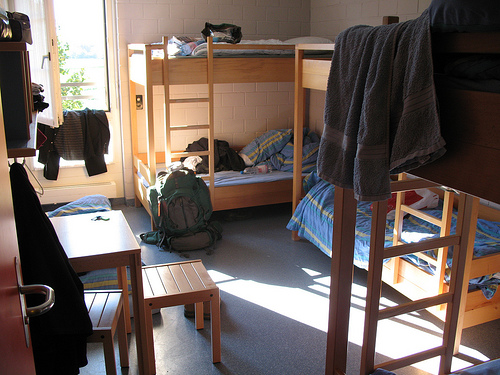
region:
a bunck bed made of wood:
[130, 20, 310, 197]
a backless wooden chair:
[150, 258, 230, 363]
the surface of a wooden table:
[57, 212, 139, 274]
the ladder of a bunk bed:
[166, 43, 219, 188]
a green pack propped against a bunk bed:
[148, 170, 234, 264]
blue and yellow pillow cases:
[245, 123, 294, 168]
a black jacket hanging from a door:
[11, 161, 109, 373]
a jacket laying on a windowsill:
[41, 109, 118, 173]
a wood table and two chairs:
[49, 213, 231, 366]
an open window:
[31, 0, 118, 102]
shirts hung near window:
[33, 55, 242, 304]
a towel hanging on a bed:
[280, 12, 496, 243]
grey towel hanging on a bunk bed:
[256, 17, 493, 237]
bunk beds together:
[113, 52, 396, 344]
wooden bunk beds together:
[98, 55, 480, 344]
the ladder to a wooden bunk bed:
[285, 135, 498, 360]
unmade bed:
[127, 1, 386, 309]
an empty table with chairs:
[58, 166, 263, 344]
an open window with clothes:
[8, 0, 337, 290]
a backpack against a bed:
[151, 187, 416, 367]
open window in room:
[37, 11, 117, 106]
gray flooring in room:
[236, 262, 318, 372]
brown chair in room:
[143, 233, 216, 317]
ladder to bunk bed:
[354, 211, 464, 365]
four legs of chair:
[144, 249, 241, 346]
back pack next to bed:
[146, 164, 220, 249]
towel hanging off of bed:
[292, 13, 455, 212]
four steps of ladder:
[375, 176, 441, 369]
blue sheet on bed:
[299, 191, 335, 250]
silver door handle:
[25, 263, 70, 324]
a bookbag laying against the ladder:
[134, 166, 236, 260]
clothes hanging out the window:
[28, 107, 134, 188]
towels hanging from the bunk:
[297, 0, 488, 202]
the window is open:
[20, 5, 140, 133]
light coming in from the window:
[43, 1, 144, 111]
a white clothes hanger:
[12, 151, 56, 207]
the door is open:
[4, 114, 62, 370]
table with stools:
[51, 205, 239, 368]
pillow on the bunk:
[239, 116, 329, 175]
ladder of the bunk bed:
[156, 28, 250, 195]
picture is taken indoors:
[26, 29, 428, 361]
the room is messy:
[38, 82, 447, 373]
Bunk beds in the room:
[150, 23, 493, 333]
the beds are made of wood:
[135, 61, 492, 313]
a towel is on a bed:
[315, 25, 457, 240]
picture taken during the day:
[31, 3, 137, 153]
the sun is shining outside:
[50, 16, 107, 121]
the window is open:
[24, 21, 73, 121]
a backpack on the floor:
[123, 162, 240, 279]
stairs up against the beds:
[183, 119, 427, 347]